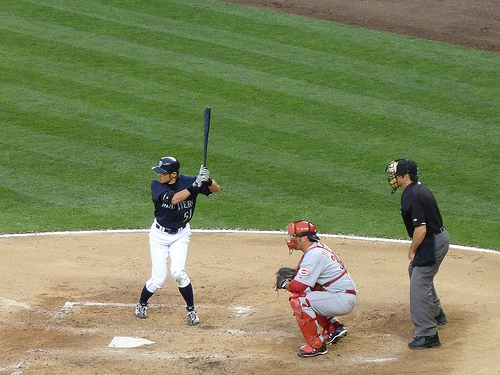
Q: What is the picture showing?
A: It is showing a field.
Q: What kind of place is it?
A: It is a field.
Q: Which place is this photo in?
A: It is at the field.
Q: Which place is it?
A: It is a field.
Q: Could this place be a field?
A: Yes, it is a field.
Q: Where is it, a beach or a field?
A: It is a field.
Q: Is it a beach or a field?
A: It is a field.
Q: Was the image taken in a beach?
A: No, the picture was taken in a field.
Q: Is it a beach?
A: No, it is a field.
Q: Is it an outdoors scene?
A: Yes, it is outdoors.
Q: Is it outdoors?
A: Yes, it is outdoors.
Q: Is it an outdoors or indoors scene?
A: It is outdoors.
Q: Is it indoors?
A: No, it is outdoors.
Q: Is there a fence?
A: No, there are no fences.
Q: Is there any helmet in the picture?
A: Yes, there is a helmet.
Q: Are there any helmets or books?
A: Yes, there is a helmet.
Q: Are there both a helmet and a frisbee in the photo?
A: No, there is a helmet but no frisbees.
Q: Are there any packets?
A: No, there are no packets.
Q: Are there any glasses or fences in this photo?
A: No, there are no fences or glasses.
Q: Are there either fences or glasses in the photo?
A: No, there are no fences or glasses.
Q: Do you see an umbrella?
A: No, there are no umbrellas.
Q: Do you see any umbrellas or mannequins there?
A: No, there are no umbrellas or mannequins.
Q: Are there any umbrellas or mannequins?
A: No, there are no umbrellas or mannequins.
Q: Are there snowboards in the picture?
A: No, there are no snowboards.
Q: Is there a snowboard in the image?
A: No, there are no snowboards.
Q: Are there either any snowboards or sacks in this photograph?
A: No, there are no snowboards or sacks.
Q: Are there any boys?
A: No, there are no boys.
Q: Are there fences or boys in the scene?
A: No, there are no boys or fences.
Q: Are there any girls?
A: No, there are no girls.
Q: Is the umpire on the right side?
A: Yes, the umpire is on the right of the image.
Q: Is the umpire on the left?
A: No, the umpire is on the right of the image.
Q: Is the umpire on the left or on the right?
A: The umpire is on the right of the image.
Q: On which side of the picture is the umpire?
A: The umpire is on the right of the image.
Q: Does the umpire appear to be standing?
A: Yes, the umpire is standing.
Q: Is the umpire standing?
A: Yes, the umpire is standing.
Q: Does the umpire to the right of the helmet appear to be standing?
A: Yes, the umpire is standing.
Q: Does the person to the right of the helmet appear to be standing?
A: Yes, the umpire is standing.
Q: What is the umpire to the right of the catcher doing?
A: The umpire is standing.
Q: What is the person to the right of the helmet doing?
A: The umpire is standing.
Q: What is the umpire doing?
A: The umpire is standing.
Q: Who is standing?
A: The umpire is standing.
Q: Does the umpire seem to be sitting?
A: No, the umpire is standing.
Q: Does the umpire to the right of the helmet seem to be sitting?
A: No, the umpire is standing.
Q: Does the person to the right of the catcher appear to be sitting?
A: No, the umpire is standing.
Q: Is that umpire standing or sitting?
A: The umpire is standing.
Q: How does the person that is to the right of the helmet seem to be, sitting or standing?
A: The umpire is standing.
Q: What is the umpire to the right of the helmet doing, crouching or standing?
A: The umpire is standing.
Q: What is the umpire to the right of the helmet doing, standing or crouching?
A: The umpire is standing.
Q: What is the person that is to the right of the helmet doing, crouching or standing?
A: The umpire is standing.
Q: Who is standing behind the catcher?
A: The umpire is standing behind the catcher.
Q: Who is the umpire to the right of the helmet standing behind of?
A: The umpire is standing behind the catcher.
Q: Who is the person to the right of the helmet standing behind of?
A: The umpire is standing behind the catcher.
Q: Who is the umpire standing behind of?
A: The umpire is standing behind the catcher.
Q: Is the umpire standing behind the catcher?
A: Yes, the umpire is standing behind the catcher.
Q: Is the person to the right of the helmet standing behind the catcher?
A: Yes, the umpire is standing behind the catcher.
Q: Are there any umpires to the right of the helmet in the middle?
A: Yes, there is an umpire to the right of the helmet.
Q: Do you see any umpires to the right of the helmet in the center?
A: Yes, there is an umpire to the right of the helmet.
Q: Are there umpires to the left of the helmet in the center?
A: No, the umpire is to the right of the helmet.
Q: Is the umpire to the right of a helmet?
A: Yes, the umpire is to the right of a helmet.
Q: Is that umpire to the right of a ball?
A: No, the umpire is to the right of a helmet.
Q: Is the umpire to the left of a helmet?
A: No, the umpire is to the right of a helmet.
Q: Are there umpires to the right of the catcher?
A: Yes, there is an umpire to the right of the catcher.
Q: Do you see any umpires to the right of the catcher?
A: Yes, there is an umpire to the right of the catcher.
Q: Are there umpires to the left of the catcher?
A: No, the umpire is to the right of the catcher.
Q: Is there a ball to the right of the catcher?
A: No, there is an umpire to the right of the catcher.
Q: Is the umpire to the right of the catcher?
A: Yes, the umpire is to the right of the catcher.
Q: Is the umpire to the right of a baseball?
A: No, the umpire is to the right of the catcher.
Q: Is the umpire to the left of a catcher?
A: No, the umpire is to the right of a catcher.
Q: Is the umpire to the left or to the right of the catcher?
A: The umpire is to the right of the catcher.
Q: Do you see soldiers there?
A: No, there are no soldiers.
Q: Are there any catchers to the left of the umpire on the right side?
A: Yes, there is a catcher to the left of the umpire.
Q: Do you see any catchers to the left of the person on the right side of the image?
A: Yes, there is a catcher to the left of the umpire.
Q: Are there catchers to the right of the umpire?
A: No, the catcher is to the left of the umpire.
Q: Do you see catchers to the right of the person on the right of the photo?
A: No, the catcher is to the left of the umpire.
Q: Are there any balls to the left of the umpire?
A: No, there is a catcher to the left of the umpire.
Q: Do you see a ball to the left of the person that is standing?
A: No, there is a catcher to the left of the umpire.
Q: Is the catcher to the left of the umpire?
A: Yes, the catcher is to the left of the umpire.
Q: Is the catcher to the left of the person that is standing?
A: Yes, the catcher is to the left of the umpire.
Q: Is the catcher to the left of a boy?
A: No, the catcher is to the left of the umpire.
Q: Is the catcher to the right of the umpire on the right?
A: No, the catcher is to the left of the umpire.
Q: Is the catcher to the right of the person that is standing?
A: No, the catcher is to the left of the umpire.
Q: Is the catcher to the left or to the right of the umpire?
A: The catcher is to the left of the umpire.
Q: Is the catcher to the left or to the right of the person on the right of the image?
A: The catcher is to the left of the umpire.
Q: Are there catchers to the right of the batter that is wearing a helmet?
A: Yes, there is a catcher to the right of the batter.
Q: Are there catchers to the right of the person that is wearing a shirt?
A: Yes, there is a catcher to the right of the batter.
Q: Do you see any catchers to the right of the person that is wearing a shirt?
A: Yes, there is a catcher to the right of the batter.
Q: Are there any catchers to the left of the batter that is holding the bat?
A: No, the catcher is to the right of the batter.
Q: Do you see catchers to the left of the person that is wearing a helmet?
A: No, the catcher is to the right of the batter.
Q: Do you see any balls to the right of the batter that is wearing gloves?
A: No, there is a catcher to the right of the batter.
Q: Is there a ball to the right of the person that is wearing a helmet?
A: No, there is a catcher to the right of the batter.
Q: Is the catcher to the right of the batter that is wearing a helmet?
A: Yes, the catcher is to the right of the batter.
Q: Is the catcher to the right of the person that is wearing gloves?
A: Yes, the catcher is to the right of the batter.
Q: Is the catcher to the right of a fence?
A: No, the catcher is to the right of the batter.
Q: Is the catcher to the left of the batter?
A: No, the catcher is to the right of the batter.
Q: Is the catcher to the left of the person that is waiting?
A: No, the catcher is to the right of the batter.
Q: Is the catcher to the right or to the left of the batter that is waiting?
A: The catcher is to the right of the batter.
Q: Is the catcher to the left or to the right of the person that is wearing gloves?
A: The catcher is to the right of the batter.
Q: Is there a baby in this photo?
A: No, there are no babies.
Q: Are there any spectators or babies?
A: No, there are no babies or spectators.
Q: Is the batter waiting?
A: Yes, the batter is waiting.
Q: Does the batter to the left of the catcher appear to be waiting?
A: Yes, the batter is waiting.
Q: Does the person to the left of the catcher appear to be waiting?
A: Yes, the batter is waiting.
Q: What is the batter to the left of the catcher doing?
A: The batter is waiting.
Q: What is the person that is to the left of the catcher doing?
A: The batter is waiting.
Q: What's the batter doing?
A: The batter is waiting.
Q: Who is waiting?
A: The batter is waiting.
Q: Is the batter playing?
A: No, the batter is waiting.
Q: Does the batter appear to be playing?
A: No, the batter is waiting.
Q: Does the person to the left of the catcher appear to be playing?
A: No, the batter is waiting.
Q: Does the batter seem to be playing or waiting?
A: The batter is waiting.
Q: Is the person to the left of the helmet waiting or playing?
A: The batter is waiting.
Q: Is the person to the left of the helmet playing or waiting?
A: The batter is waiting.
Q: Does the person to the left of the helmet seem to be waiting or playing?
A: The batter is waiting.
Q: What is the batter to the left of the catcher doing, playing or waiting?
A: The batter is waiting.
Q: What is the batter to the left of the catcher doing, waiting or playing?
A: The batter is waiting.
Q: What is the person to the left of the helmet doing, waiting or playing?
A: The batter is waiting.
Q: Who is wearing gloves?
A: The batter is wearing gloves.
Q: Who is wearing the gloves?
A: The batter is wearing gloves.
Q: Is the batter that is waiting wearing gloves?
A: Yes, the batter is wearing gloves.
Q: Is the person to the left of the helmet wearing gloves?
A: Yes, the batter is wearing gloves.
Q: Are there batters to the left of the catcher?
A: Yes, there is a batter to the left of the catcher.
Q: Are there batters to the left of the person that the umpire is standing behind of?
A: Yes, there is a batter to the left of the catcher.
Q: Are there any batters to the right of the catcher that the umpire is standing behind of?
A: No, the batter is to the left of the catcher.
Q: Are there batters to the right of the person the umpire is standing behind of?
A: No, the batter is to the left of the catcher.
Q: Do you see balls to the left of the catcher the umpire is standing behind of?
A: No, there is a batter to the left of the catcher.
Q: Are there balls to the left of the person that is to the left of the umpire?
A: No, there is a batter to the left of the catcher.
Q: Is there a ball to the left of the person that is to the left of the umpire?
A: No, there is a batter to the left of the catcher.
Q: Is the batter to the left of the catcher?
A: Yes, the batter is to the left of the catcher.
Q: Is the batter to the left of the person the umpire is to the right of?
A: Yes, the batter is to the left of the catcher.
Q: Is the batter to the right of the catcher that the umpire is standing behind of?
A: No, the batter is to the left of the catcher.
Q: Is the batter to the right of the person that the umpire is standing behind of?
A: No, the batter is to the left of the catcher.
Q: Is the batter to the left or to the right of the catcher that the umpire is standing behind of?
A: The batter is to the left of the catcher.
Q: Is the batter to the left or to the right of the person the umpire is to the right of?
A: The batter is to the left of the catcher.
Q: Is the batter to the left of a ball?
A: No, the batter is to the left of the helmet.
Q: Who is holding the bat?
A: The batter is holding the bat.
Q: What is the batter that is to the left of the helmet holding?
A: The batter is holding the bat.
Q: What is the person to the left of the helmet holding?
A: The batter is holding the bat.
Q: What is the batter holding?
A: The batter is holding the bat.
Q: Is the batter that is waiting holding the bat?
A: Yes, the batter is holding the bat.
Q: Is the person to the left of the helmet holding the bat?
A: Yes, the batter is holding the bat.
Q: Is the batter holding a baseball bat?
A: No, the batter is holding the bat.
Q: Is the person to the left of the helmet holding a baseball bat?
A: No, the batter is holding the bat.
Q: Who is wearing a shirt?
A: The batter is wearing a shirt.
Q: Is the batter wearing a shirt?
A: Yes, the batter is wearing a shirt.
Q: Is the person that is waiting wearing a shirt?
A: Yes, the batter is wearing a shirt.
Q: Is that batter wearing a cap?
A: No, the batter is wearing a shirt.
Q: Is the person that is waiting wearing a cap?
A: No, the batter is wearing a shirt.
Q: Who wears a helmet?
A: The batter wears a helmet.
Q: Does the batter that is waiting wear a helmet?
A: Yes, the batter wears a helmet.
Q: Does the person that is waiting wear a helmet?
A: Yes, the batter wears a helmet.